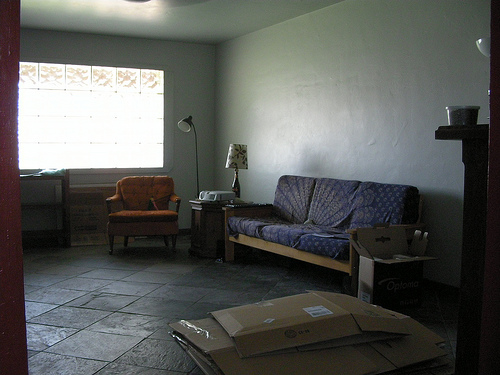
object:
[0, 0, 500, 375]
room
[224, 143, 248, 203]
lamp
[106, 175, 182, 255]
chair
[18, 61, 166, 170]
window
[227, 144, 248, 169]
pattern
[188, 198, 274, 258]
table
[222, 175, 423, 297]
couch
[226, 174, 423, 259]
futon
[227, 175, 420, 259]
cover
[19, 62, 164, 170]
squares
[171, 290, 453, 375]
pile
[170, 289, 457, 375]
boxes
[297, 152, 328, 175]
shade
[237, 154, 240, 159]
leaves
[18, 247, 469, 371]
floor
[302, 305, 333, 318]
label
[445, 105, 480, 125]
container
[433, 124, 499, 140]
mantle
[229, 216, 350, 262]
cushions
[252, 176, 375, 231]
patterns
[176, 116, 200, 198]
lamp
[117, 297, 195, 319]
tile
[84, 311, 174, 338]
tile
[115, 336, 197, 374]
tile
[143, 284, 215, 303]
tile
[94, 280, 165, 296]
tile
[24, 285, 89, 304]
tile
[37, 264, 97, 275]
tile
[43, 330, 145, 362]
tile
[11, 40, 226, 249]
wall